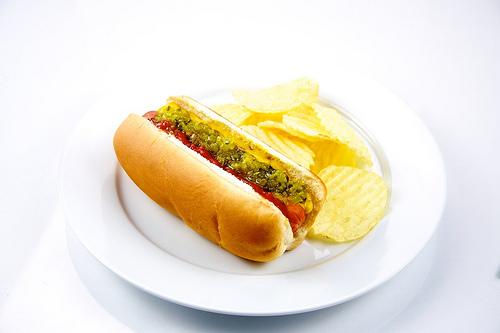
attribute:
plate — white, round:
[64, 81, 449, 323]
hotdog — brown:
[112, 95, 327, 264]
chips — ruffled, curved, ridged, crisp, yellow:
[215, 77, 390, 243]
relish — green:
[163, 106, 316, 208]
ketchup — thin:
[153, 119, 290, 218]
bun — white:
[121, 114, 287, 267]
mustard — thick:
[200, 117, 231, 136]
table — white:
[3, 0, 500, 332]